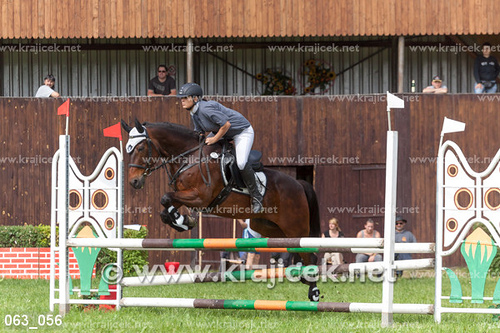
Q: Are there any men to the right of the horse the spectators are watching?
A: Yes, there is a man to the right of the horse.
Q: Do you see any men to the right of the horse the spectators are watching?
A: Yes, there is a man to the right of the horse.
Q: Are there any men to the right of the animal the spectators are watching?
A: Yes, there is a man to the right of the horse.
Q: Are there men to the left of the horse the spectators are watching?
A: No, the man is to the right of the horse.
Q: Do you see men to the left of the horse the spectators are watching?
A: No, the man is to the right of the horse.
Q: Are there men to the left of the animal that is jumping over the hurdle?
A: No, the man is to the right of the horse.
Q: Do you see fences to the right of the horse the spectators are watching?
A: No, there is a man to the right of the horse.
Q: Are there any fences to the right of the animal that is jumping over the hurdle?
A: No, there is a man to the right of the horse.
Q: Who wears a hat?
A: The man wears a hat.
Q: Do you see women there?
A: Yes, there is a woman.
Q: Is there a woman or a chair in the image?
A: Yes, there is a woman.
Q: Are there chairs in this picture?
A: No, there are no chairs.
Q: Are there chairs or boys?
A: No, there are no chairs or boys.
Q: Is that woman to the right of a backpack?
A: No, the woman is to the right of the flag.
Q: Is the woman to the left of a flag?
A: Yes, the woman is to the left of a flag.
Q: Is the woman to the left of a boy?
A: No, the woman is to the left of a flag.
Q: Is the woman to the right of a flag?
A: No, the woman is to the left of a flag.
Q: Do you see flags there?
A: Yes, there is a flag.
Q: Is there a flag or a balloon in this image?
A: Yes, there is a flag.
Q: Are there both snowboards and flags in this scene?
A: No, there is a flag but no snowboards.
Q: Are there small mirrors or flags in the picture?
A: Yes, there is a small flag.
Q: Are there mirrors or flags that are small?
A: Yes, the flag is small.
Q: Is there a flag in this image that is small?
A: Yes, there is a small flag.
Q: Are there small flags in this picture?
A: Yes, there is a small flag.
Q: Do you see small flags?
A: Yes, there is a small flag.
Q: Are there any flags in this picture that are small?
A: Yes, there is a flag that is small.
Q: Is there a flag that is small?
A: Yes, there is a flag that is small.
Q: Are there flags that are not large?
A: Yes, there is a small flag.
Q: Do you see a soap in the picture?
A: No, there are no soaps.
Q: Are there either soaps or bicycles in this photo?
A: No, there are no soaps or bicycles.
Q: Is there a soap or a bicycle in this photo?
A: No, there are no soaps or bicycles.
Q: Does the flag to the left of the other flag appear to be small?
A: Yes, the flag is small.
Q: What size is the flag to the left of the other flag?
A: The flag is small.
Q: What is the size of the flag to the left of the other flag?
A: The flag is small.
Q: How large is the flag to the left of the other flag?
A: The flag is small.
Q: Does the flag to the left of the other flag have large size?
A: No, the flag is small.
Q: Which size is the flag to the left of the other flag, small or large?
A: The flag is small.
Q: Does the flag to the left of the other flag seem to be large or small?
A: The flag is small.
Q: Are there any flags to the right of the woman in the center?
A: Yes, there is a flag to the right of the woman.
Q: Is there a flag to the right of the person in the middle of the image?
A: Yes, there is a flag to the right of the woman.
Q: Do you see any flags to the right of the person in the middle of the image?
A: Yes, there is a flag to the right of the woman.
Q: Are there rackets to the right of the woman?
A: No, there is a flag to the right of the woman.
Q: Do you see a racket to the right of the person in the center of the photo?
A: No, there is a flag to the right of the woman.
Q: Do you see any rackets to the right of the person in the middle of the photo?
A: No, there is a flag to the right of the woman.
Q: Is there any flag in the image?
A: Yes, there is a flag.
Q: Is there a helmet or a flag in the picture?
A: Yes, there is a flag.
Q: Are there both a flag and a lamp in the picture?
A: No, there is a flag but no lamps.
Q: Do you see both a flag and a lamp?
A: No, there is a flag but no lamps.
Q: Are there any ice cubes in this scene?
A: No, there are no ice cubes.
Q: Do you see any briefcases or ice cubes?
A: No, there are no ice cubes or briefcases.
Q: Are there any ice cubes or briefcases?
A: No, there are no ice cubes or briefcases.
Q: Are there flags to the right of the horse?
A: Yes, there is a flag to the right of the horse.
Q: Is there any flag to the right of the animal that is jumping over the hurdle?
A: Yes, there is a flag to the right of the horse.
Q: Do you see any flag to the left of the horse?
A: No, the flag is to the right of the horse.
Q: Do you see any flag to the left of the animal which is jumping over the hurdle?
A: No, the flag is to the right of the horse.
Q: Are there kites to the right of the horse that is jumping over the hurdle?
A: No, there is a flag to the right of the horse.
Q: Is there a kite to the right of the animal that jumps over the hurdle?
A: No, there is a flag to the right of the horse.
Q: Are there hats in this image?
A: Yes, there is a hat.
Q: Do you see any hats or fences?
A: Yes, there is a hat.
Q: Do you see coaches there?
A: No, there are no coaches.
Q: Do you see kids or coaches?
A: No, there are no coaches or kids.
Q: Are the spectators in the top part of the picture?
A: Yes, the spectators are in the top of the image.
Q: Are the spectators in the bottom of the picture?
A: No, the spectators are in the top of the image.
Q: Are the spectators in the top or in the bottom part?
A: The spectators are in the top of the image.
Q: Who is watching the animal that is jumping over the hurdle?
A: The spectators are watching the horse.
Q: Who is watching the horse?
A: The spectators are watching the horse.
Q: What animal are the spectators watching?
A: The spectators are watching the horse.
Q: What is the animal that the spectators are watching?
A: The animal is a horse.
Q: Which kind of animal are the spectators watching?
A: The spectators are watching the horse.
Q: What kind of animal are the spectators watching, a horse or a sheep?
A: The spectators are watching a horse.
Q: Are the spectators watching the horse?
A: Yes, the spectators are watching the horse.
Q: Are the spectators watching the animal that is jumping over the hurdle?
A: Yes, the spectators are watching the horse.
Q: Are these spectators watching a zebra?
A: No, the spectators are watching the horse.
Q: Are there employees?
A: No, there are no employees.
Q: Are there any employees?
A: No, there are no employees.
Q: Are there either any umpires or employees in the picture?
A: No, there are no employees or umpires.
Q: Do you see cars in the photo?
A: No, there are no cars.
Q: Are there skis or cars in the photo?
A: No, there are no cars or skis.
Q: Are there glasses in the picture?
A: No, there are no glasses.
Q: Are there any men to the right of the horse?
A: Yes, there is a man to the right of the horse.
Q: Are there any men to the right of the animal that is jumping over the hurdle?
A: Yes, there is a man to the right of the horse.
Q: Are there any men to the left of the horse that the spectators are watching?
A: No, the man is to the right of the horse.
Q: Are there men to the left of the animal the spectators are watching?
A: No, the man is to the right of the horse.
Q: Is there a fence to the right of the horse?
A: No, there is a man to the right of the horse.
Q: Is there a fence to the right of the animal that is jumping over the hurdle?
A: No, there is a man to the right of the horse.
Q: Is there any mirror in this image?
A: No, there are no mirrors.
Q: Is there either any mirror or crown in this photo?
A: No, there are no mirrors or crowns.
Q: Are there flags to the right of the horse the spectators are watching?
A: Yes, there are flags to the right of the horse.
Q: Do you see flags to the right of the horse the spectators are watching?
A: Yes, there are flags to the right of the horse.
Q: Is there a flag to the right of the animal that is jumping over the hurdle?
A: Yes, there are flags to the right of the horse.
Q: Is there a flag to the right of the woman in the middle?
A: Yes, there are flags to the right of the woman.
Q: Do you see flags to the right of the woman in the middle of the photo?
A: Yes, there are flags to the right of the woman.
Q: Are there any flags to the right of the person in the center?
A: Yes, there are flags to the right of the woman.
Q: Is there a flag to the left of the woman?
A: No, the flags are to the right of the woman.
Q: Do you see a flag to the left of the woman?
A: No, the flags are to the right of the woman.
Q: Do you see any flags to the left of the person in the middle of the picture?
A: No, the flags are to the right of the woman.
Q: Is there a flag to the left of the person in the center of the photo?
A: No, the flags are to the right of the woman.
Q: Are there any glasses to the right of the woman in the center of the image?
A: No, there are flags to the right of the woman.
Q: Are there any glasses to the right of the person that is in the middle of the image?
A: No, there are flags to the right of the woman.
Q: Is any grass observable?
A: Yes, there is grass.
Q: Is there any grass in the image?
A: Yes, there is grass.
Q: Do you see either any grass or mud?
A: Yes, there is grass.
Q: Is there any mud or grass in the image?
A: Yes, there is grass.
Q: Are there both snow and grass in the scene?
A: No, there is grass but no snow.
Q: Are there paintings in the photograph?
A: No, there are no paintings.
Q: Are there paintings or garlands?
A: No, there are no paintings or garlands.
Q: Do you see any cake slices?
A: No, there are no cake slices.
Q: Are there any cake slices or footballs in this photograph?
A: No, there are no cake slices or footballs.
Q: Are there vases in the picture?
A: No, there are no vases.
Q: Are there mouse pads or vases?
A: No, there are no vases or mouse pads.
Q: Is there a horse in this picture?
A: Yes, there is a horse.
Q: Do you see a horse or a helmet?
A: Yes, there is a horse.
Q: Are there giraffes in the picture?
A: No, there are no giraffes.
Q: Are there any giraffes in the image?
A: No, there are no giraffes.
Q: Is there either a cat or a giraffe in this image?
A: No, there are no giraffes or cats.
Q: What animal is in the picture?
A: The animal is a horse.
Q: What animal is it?
A: The animal is a horse.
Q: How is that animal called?
A: This is a horse.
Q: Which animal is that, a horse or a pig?
A: This is a horse.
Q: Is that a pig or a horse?
A: That is a horse.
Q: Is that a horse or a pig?
A: That is a horse.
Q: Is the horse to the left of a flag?
A: Yes, the horse is to the left of a flag.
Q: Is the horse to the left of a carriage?
A: No, the horse is to the left of a flag.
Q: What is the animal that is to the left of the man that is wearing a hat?
A: The animal is a horse.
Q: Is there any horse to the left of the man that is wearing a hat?
A: Yes, there is a horse to the left of the man.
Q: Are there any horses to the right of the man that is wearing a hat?
A: No, the horse is to the left of the man.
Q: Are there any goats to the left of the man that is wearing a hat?
A: No, there is a horse to the left of the man.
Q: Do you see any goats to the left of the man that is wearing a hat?
A: No, there is a horse to the left of the man.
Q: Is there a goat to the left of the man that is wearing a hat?
A: No, there is a horse to the left of the man.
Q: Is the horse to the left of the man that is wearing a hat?
A: Yes, the horse is to the left of the man.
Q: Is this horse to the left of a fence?
A: No, the horse is to the left of the man.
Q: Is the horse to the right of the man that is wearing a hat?
A: No, the horse is to the left of the man.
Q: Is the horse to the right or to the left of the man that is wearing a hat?
A: The horse is to the left of the man.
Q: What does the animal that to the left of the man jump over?
A: The horse jumps over the hurdle.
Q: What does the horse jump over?
A: The horse jumps over the hurdle.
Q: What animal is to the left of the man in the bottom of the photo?
A: The animal is a horse.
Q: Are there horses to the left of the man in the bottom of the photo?
A: Yes, there is a horse to the left of the man.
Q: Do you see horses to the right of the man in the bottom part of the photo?
A: No, the horse is to the left of the man.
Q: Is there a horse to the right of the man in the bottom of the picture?
A: No, the horse is to the left of the man.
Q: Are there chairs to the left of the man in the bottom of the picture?
A: No, there is a horse to the left of the man.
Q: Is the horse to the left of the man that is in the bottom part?
A: Yes, the horse is to the left of the man.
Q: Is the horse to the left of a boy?
A: No, the horse is to the left of the man.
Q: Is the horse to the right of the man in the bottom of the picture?
A: No, the horse is to the left of the man.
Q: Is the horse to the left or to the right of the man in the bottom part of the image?
A: The horse is to the left of the man.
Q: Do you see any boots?
A: Yes, there are boots.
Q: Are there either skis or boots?
A: Yes, there are boots.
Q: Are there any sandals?
A: No, there are no sandals.